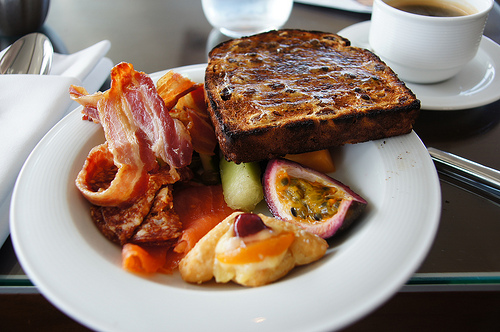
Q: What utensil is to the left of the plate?
A: Spoon.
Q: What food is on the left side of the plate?
A: Bacon.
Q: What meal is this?
A: Breakfast.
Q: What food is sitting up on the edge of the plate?
A: Toast.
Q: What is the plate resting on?
A: Table.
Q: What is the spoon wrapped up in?
A: Napkin.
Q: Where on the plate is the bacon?
A: Left.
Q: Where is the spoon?
A: In the napkin.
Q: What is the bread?
A: French Toast.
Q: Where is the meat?
A: On the plate.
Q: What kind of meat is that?
A: Bacon.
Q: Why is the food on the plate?
A: For breakfast.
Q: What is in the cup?
A: Coffee.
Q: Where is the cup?
A: On the saucer.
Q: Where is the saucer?
A: On the table.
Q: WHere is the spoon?
A: In a napkin.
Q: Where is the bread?
A: On the plate.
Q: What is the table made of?
A: Wood.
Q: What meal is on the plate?
A: Breakfast.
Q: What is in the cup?
A: Coffee.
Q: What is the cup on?
A: Saucer.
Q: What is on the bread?
A: Jelly.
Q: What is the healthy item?
A: Fruit.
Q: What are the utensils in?
A: Napkin.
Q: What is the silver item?
A: Spoon.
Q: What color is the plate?
A: White.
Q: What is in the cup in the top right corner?
A: Coffee.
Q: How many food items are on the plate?
A: Eight.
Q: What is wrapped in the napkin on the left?
A: Spoon.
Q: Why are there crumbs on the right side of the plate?
A: Because of the toast.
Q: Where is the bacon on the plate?
A: On the left side.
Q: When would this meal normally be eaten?
A: Morning.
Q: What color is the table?
A: Brown.